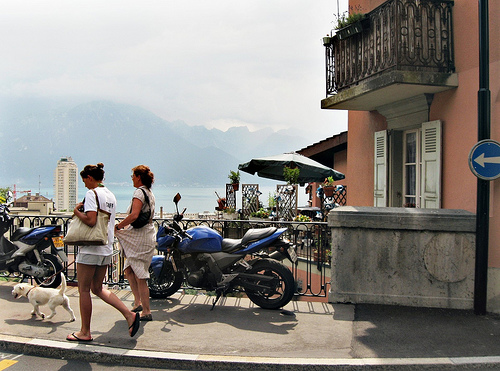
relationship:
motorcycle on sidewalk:
[145, 216, 297, 318] [0, 277, 497, 364]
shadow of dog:
[11, 314, 77, 337] [11, 278, 74, 328]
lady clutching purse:
[71, 162, 153, 343] [62, 208, 111, 247]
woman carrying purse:
[65, 162, 140, 343] [61, 191, 113, 242]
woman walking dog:
[62, 158, 142, 346] [8, 272, 76, 324]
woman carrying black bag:
[110, 164, 158, 324] [125, 185, 151, 227]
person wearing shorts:
[60, 161, 139, 342] [73, 250, 114, 266]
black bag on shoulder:
[127, 186, 152, 228] [137, 185, 144, 195]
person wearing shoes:
[113, 162, 158, 322] [130, 301, 156, 324]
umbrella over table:
[237, 150, 346, 200] [263, 209, 325, 281]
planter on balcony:
[332, 4, 374, 39] [317, 1, 459, 133]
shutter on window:
[370, 127, 387, 205] [370, 118, 445, 210]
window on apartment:
[370, 118, 445, 210] [320, 0, 499, 316]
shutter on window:
[419, 117, 441, 208] [395, 130, 430, 209]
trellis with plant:
[224, 182, 236, 211] [225, 169, 240, 189]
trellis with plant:
[240, 183, 257, 213] [283, 160, 299, 183]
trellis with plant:
[278, 185, 297, 220] [320, 174, 335, 197]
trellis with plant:
[320, 187, 348, 247] [255, 208, 270, 225]